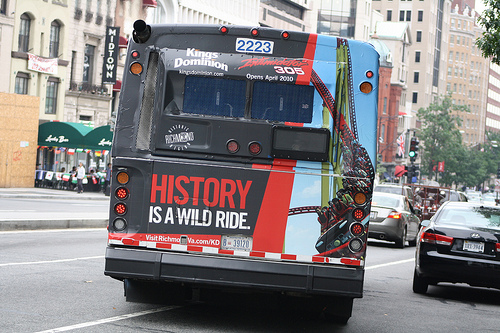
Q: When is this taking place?
A: Daytime.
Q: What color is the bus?
A: Red, blue, black.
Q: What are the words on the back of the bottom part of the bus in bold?
A: History is a wild ride.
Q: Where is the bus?
A: Street.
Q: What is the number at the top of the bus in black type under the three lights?
A: 2223.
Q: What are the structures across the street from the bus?
A: Buildings.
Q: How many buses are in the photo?
A: One.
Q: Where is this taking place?
A: City street.